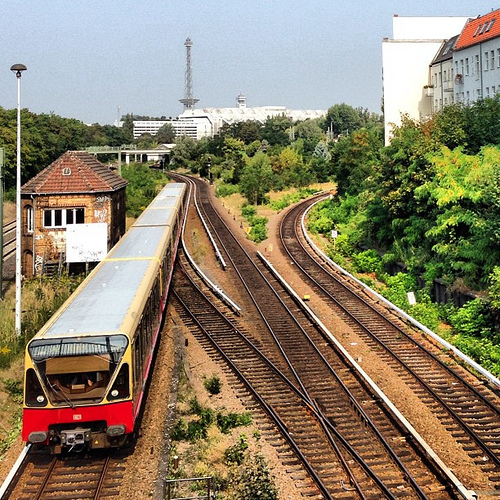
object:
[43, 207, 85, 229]
white pane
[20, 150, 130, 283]
building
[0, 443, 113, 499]
tracks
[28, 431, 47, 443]
bumper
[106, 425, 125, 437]
bumper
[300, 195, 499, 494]
railing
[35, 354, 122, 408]
window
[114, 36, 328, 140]
building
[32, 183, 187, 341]
train top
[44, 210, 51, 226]
window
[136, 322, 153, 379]
glass window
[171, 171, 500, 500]
railroad tracks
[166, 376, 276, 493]
weeds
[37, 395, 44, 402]
headlight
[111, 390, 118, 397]
headlight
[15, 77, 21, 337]
lightpole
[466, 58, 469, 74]
windows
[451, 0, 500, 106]
building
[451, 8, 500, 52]
roof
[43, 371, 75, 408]
wiper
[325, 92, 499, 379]
bush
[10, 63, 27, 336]
pole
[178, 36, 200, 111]
tower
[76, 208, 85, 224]
window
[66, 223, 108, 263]
sign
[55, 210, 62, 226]
window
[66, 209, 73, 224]
window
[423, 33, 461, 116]
building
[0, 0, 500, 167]
background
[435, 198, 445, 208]
part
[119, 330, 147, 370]
part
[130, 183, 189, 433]
side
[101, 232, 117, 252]
part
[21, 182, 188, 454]
car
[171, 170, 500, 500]
tracks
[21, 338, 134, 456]
front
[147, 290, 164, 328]
window